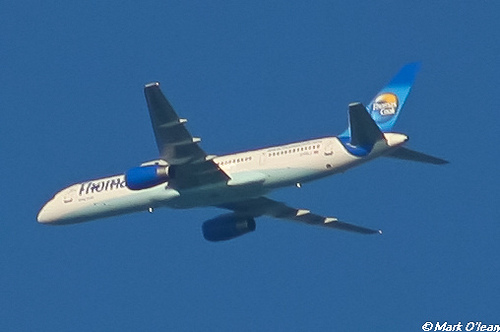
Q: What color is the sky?
A: Blue.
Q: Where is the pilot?
A: In the cockpit.